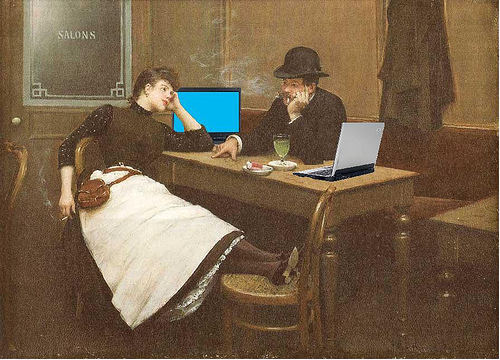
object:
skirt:
[79, 171, 242, 330]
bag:
[75, 176, 112, 212]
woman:
[58, 64, 303, 327]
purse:
[78, 161, 128, 211]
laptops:
[166, 85, 240, 145]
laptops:
[289, 115, 401, 185]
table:
[135, 128, 427, 331]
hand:
[54, 192, 79, 224]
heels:
[270, 231, 312, 288]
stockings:
[233, 242, 275, 277]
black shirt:
[49, 99, 216, 189]